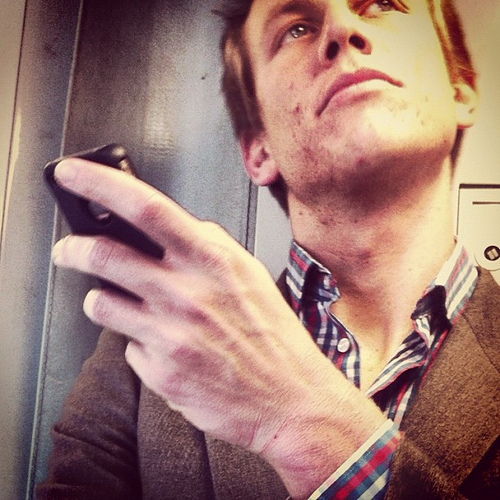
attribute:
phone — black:
[40, 138, 162, 312]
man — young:
[235, 6, 454, 236]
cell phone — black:
[30, 127, 201, 297]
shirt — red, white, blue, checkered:
[262, 233, 472, 421]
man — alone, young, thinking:
[248, 11, 444, 243]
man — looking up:
[264, 40, 448, 239]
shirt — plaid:
[255, 250, 475, 400]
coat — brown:
[101, 277, 480, 474]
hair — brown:
[195, 2, 274, 127]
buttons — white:
[296, 250, 358, 370]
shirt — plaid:
[279, 234, 465, 422]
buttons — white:
[300, 259, 352, 355]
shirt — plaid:
[284, 242, 438, 492]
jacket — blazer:
[85, 270, 489, 473]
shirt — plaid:
[259, 236, 440, 460]